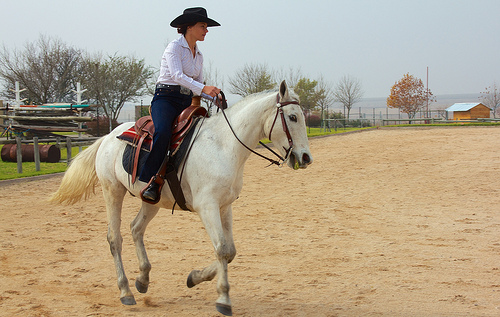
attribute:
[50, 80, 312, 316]
horse — white, moving, trotting, pretty, galloping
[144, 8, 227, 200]
person — riding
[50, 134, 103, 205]
tail — wagging, blonde, yellow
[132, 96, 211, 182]
saddle — brown, leather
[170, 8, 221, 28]
hat — black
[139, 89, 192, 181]
jeans — dark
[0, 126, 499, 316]
field — dirt, sandy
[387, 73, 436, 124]
tree — orange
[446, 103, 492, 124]
structure — brown, yellow, small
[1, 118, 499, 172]
fence — wooden, metal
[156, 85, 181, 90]
belt — black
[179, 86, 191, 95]
buckle — silver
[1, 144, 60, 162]
cylinder — rusty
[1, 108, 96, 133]
poles — wooden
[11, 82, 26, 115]
support — white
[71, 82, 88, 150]
support — white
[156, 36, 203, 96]
shirt — white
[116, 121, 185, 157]
blanket — striped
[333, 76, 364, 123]
tree — leafless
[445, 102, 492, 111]
roof — tin